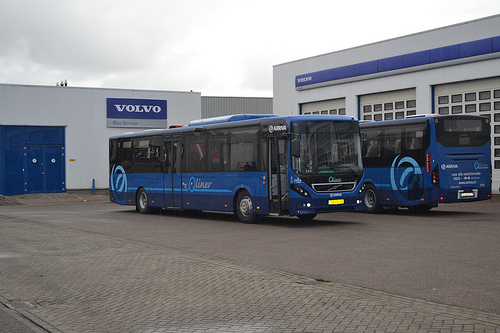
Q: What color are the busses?
A: Blue.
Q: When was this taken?
A: During the day.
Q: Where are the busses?
A: In parking lot.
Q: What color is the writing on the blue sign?
A: White.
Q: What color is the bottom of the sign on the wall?
A: Gray.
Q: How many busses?
A: Two.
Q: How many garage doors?
A: Three.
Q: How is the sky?
A: Cloudy.